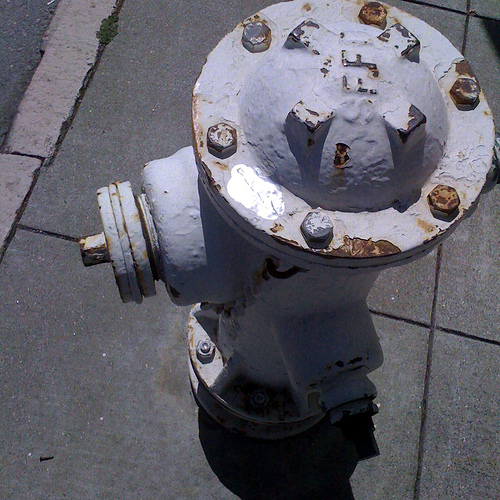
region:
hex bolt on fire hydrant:
[361, 2, 391, 27]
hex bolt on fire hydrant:
[241, 24, 273, 48]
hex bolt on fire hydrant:
[204, 119, 239, 155]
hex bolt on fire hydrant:
[298, 208, 335, 241]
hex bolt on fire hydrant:
[426, 183, 461, 218]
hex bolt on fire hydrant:
[193, 338, 217, 365]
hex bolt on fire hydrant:
[249, 390, 268, 410]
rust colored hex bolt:
[358, 2, 387, 27]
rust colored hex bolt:
[426, 183, 462, 215]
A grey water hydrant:
[63, 7, 494, 454]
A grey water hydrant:
[66, 9, 491, 459]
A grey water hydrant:
[58, 5, 486, 455]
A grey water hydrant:
[66, 6, 488, 446]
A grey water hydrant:
[67, 11, 469, 443]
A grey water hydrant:
[68, 3, 485, 478]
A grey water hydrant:
[58, 7, 479, 449]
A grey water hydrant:
[67, 10, 482, 450]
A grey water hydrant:
[73, 9, 490, 446]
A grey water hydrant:
[70, 9, 486, 451]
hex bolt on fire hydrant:
[297, 210, 332, 245]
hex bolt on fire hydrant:
[192, 336, 212, 356]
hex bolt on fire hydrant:
[451, 75, 478, 105]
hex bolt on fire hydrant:
[243, 381, 275, 411]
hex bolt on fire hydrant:
[355, 3, 392, 25]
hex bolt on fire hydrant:
[241, 20, 275, 50]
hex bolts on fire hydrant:
[300, 184, 460, 240]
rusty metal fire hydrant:
[142, 32, 483, 497]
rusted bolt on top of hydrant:
[305, 213, 327, 248]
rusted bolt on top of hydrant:
[427, 185, 459, 232]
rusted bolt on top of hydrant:
[452, 72, 479, 104]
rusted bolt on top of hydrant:
[362, 5, 388, 20]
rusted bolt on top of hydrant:
[239, 27, 279, 52]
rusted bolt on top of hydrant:
[190, 86, 247, 155]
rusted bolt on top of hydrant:
[197, 344, 227, 365]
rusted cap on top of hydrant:
[72, 171, 158, 308]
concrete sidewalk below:
[46, 24, 495, 491]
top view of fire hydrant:
[75, 5, 495, 445]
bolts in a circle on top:
[207, 5, 477, 243]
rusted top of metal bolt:
[431, 183, 461, 212]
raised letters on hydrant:
[340, 34, 377, 125]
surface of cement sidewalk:
[15, 5, 496, 497]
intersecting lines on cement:
[388, 266, 493, 498]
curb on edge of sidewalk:
[0, 2, 115, 191]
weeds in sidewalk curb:
[56, 2, 126, 140]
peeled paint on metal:
[333, 236, 408, 259]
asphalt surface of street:
[0, 3, 50, 139]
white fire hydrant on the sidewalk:
[138, 12, 311, 482]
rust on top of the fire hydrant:
[184, 11, 472, 231]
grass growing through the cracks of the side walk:
[88, 14, 134, 47]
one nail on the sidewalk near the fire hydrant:
[35, 445, 58, 470]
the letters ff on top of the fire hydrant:
[331, 49, 383, 99]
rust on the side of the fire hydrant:
[76, 171, 140, 306]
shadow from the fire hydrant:
[204, 403, 287, 499]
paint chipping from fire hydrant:
[295, 23, 426, 130]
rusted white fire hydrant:
[133, 27, 375, 497]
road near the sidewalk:
[0, 2, 42, 73]